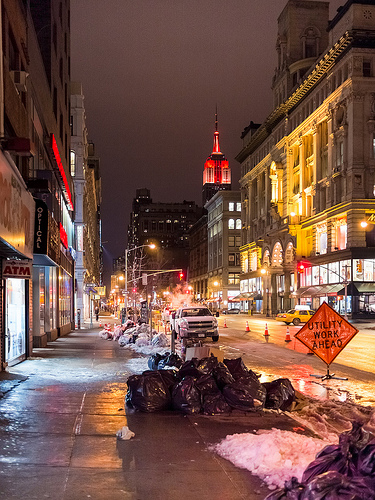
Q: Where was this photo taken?
A: On a city street.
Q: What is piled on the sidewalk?
A: Garbage Bags.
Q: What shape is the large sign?
A: Diamond.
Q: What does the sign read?
A: Utility work ahead.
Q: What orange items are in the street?
A: Cones.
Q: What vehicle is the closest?
A: Pickup truck.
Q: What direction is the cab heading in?
A: To the right.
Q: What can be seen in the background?
A: Buildings.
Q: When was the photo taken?
A: Nighttime.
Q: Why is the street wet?
A: There is melted snow on it.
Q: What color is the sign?
A: Orange.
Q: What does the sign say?
A: Utility Work Ahead.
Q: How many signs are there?
A: One.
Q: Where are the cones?
A: In the street.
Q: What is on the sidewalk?
A: Trash Bags.